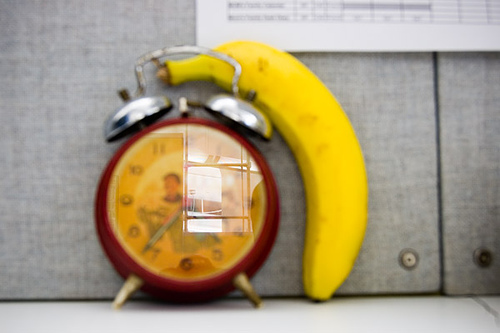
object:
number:
[150, 141, 168, 157]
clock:
[93, 45, 279, 308]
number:
[116, 193, 135, 208]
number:
[130, 163, 144, 177]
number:
[180, 257, 195, 270]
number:
[208, 249, 225, 263]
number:
[126, 224, 144, 238]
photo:
[0, 0, 499, 331]